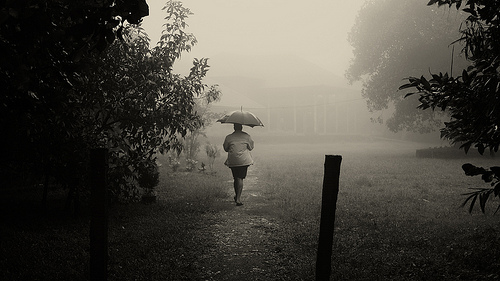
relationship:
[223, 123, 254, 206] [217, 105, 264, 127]
woman with umbrella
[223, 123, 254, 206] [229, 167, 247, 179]
woman wearing skirt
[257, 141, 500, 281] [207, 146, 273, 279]
grass beside path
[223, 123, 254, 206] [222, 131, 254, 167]
woman wearing coat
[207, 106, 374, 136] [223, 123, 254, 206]
building in front of woman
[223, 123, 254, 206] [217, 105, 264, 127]
woman holding umbrella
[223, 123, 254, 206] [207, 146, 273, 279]
woman walking down path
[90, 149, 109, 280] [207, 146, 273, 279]
post next to path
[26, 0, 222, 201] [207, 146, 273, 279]
tree next to path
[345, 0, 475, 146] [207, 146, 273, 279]
tree next to path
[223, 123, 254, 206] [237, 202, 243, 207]
woman wearing shoe